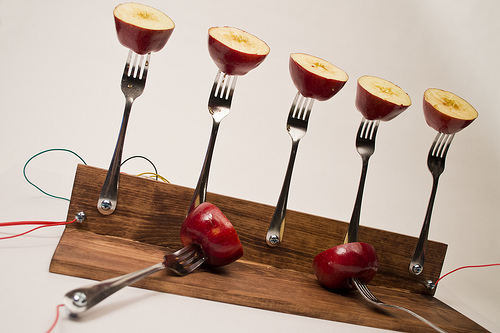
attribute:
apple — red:
[307, 235, 376, 297]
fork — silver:
[92, 50, 159, 216]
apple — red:
[110, 1, 177, 57]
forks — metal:
[76, 133, 487, 198]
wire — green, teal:
[11, 144, 90, 203]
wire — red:
[1, 203, 70, 254]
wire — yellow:
[137, 170, 170, 185]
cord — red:
[432, 259, 499, 278]